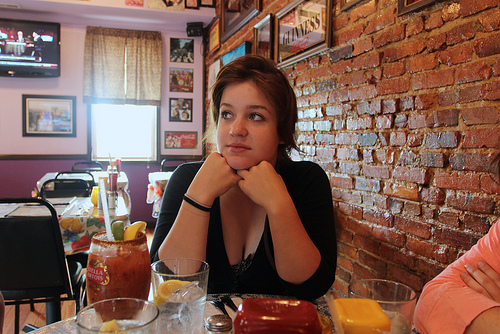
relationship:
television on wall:
[0, 17, 62, 79] [0, 1, 217, 226]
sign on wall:
[268, 1, 333, 69] [204, 1, 498, 308]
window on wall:
[87, 29, 163, 162] [0, 1, 217, 226]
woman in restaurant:
[148, 56, 336, 301] [0, 1, 499, 333]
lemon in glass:
[157, 278, 189, 300] [148, 256, 211, 334]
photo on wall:
[21, 93, 78, 138] [0, 1, 217, 226]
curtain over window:
[84, 26, 164, 106] [87, 29, 163, 162]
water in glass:
[154, 294, 206, 333] [148, 256, 211, 334]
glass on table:
[87, 226, 152, 325] [22, 292, 420, 333]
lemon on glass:
[126, 220, 147, 243] [87, 226, 152, 325]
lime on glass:
[111, 221, 124, 241] [87, 226, 152, 325]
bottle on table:
[236, 293, 322, 333] [22, 292, 420, 333]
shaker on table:
[206, 315, 232, 334] [22, 292, 420, 333]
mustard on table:
[331, 297, 390, 333] [22, 292, 420, 333]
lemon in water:
[157, 278, 189, 300] [154, 294, 206, 333]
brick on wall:
[409, 68, 455, 91] [204, 1, 498, 308]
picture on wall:
[171, 37, 196, 63] [0, 1, 217, 226]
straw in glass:
[98, 178, 114, 241] [87, 226, 152, 325]